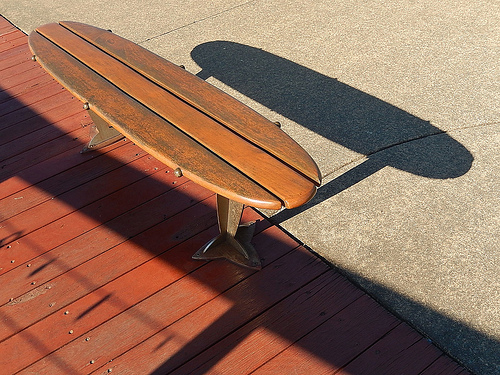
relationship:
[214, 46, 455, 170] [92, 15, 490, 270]
shadow on ground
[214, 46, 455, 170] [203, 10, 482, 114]
shadow on walkway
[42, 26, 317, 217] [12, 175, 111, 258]
bench on top of boards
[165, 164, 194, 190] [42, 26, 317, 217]
peg in bench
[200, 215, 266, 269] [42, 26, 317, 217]
leg on bench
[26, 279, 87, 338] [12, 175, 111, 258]
holes in boards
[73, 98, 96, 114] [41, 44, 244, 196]
screws on board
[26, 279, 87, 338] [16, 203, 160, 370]
holes on deck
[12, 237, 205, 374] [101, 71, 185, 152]
shadow on deck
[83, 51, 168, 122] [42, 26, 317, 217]
slats on bench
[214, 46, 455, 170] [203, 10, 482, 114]
shadow on concrete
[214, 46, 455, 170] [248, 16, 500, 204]
shadow on concrete